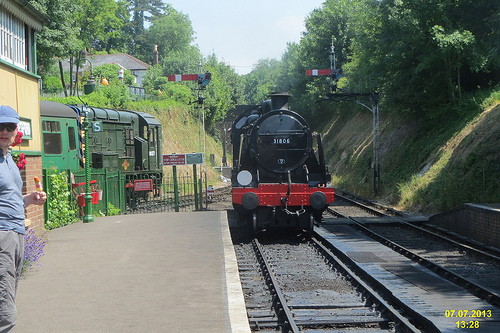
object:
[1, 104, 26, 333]
woman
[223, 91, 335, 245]
train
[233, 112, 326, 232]
front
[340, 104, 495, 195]
grass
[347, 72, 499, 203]
hill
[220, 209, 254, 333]
line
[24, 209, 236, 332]
platform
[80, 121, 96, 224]
pole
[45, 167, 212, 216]
fence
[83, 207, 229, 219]
edge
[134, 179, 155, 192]
sign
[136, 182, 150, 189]
words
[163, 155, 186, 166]
sign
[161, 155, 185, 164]
words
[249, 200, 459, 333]
track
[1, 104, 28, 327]
person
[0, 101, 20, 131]
hat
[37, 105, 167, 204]
train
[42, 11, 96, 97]
trees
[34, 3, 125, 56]
leaves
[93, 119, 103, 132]
s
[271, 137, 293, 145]
number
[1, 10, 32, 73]
windows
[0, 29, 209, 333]
train station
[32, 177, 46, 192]
popsicle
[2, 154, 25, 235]
shirt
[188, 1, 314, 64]
sky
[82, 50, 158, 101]
house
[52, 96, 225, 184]
hill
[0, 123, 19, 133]
sunglasses